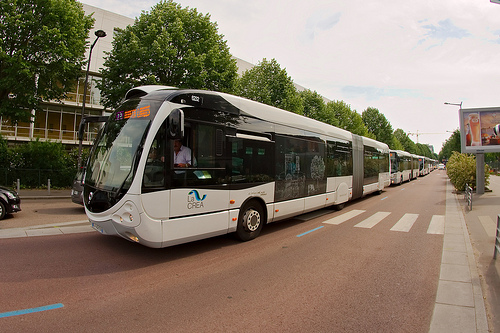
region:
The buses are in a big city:
[26, 15, 488, 316]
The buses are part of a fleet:
[18, 7, 498, 318]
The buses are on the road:
[15, 23, 490, 308]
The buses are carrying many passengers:
[20, 35, 471, 325]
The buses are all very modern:
[20, 26, 495, 318]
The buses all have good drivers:
[26, 30, 487, 305]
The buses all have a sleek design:
[15, 35, 482, 303]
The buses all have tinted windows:
[7, 27, 469, 313]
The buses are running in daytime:
[30, 33, 482, 308]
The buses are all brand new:
[37, 33, 476, 320]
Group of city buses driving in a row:
[82, 84, 439, 249]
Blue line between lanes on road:
[1, 295, 66, 320]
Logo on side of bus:
[186, 188, 207, 212]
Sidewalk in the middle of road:
[296, 208, 445, 235]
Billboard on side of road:
[458, 105, 498, 193]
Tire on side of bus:
[237, 196, 267, 240]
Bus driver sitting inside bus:
[161, 133, 196, 183]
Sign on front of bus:
[103, 106, 151, 118]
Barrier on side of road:
[462, 184, 474, 211]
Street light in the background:
[441, 99, 464, 109]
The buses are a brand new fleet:
[30, 25, 470, 326]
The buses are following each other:
[35, 20, 466, 330]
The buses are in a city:
[17, 20, 487, 330]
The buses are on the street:
[37, 27, 493, 324]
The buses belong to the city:
[31, 40, 479, 331]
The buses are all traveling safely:
[36, 20, 468, 320]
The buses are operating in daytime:
[35, 23, 477, 309]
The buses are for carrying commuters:
[50, 28, 477, 330]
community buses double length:
[81, 76, 440, 244]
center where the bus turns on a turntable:
[346, 121, 369, 206]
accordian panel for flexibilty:
[348, 122, 369, 205]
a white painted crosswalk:
[316, 202, 448, 242]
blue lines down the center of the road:
[6, 206, 349, 326]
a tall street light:
[81, 18, 111, 183]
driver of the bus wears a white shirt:
[163, 129, 195, 183]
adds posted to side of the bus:
[269, 129, 333, 201]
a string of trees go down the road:
[1, 0, 443, 162]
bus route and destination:
[96, 99, 155, 130]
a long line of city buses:
[81, 76, 442, 258]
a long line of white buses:
[83, 78, 440, 254]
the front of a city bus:
[87, 105, 158, 240]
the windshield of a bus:
[86, 122, 144, 187]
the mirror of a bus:
[164, 106, 187, 139]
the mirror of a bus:
[72, 112, 88, 145]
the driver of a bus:
[161, 138, 199, 173]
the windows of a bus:
[232, 129, 272, 181]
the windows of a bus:
[327, 139, 352, 178]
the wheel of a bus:
[231, 192, 271, 242]